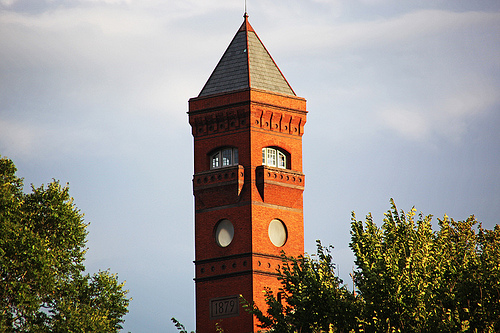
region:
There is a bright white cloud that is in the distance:
[408, 76, 440, 142]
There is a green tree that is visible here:
[413, 248, 438, 285]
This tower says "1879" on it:
[206, 294, 259, 331]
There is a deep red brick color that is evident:
[261, 183, 287, 236]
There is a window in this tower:
[263, 148, 297, 152]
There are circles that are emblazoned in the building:
[261, 251, 271, 275]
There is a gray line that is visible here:
[256, 193, 271, 226]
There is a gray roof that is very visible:
[273, 75, 280, 92]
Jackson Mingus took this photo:
[115, 93, 325, 310]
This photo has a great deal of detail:
[104, 86, 331, 306]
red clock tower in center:
[198, 8, 294, 326]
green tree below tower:
[278, 198, 468, 331]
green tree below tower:
[2, 170, 76, 327]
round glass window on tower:
[262, 212, 287, 250]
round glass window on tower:
[215, 220, 235, 245]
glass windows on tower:
[257, 145, 287, 165]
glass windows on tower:
[196, 150, 236, 170]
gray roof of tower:
[205, 20, 285, 95]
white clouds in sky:
[340, 45, 450, 130]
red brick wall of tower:
[198, 112, 255, 149]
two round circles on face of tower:
[203, 210, 291, 252]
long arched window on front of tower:
[255, 136, 296, 173]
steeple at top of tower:
[180, 1, 307, 103]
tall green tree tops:
[190, 193, 498, 331]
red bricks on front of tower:
[285, 215, 303, 230]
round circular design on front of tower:
[266, 166, 304, 187]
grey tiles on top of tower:
[256, 58, 273, 80]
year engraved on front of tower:
[203, 290, 248, 321]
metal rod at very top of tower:
[238, 0, 254, 18]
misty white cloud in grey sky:
[368, 84, 489, 158]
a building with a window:
[176, 41, 353, 293]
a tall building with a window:
[179, 36, 358, 331]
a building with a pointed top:
[187, 9, 319, 209]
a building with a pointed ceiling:
[194, 7, 307, 214]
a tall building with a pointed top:
[182, 34, 298, 276]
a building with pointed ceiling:
[200, 9, 311, 190]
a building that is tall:
[155, 43, 329, 332]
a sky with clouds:
[47, 21, 494, 299]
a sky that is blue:
[33, 18, 485, 175]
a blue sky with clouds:
[102, 16, 414, 161]